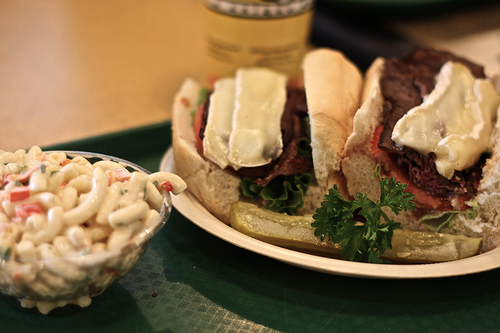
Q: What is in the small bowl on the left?
A: Macaroni Salad.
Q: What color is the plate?
A: White.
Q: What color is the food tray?
A: Green.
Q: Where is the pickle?
A: Plate.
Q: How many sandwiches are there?
A: 2.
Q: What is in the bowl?
A: Macaroni salad.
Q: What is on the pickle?
A: Parsley.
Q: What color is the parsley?
A: Green.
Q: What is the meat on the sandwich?
A: Roast beef.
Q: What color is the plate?
A: White.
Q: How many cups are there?
A: One.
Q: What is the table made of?
A: Wood.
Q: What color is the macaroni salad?
A: Pale yellow.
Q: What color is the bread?
A: Brown.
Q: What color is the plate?
A: White.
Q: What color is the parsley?
A: Green.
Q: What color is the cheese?
A: White.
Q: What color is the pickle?
A: Bright green.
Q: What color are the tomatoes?
A: Red.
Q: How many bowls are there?
A: One.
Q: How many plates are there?
A: One.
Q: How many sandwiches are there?
A: 2.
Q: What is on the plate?
A: A sandwich.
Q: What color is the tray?
A: Green.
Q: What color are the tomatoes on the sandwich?
A: Red.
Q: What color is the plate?
A: White.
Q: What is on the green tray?
A: Lunch.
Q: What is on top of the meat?
A: Mayonnaise.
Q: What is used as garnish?
A: A sprig of parsley.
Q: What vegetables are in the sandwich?
A: Lettuce and tomatoes.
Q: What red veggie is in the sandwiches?
A: Tomatoes.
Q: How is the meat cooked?
A: It has been browned.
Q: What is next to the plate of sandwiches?
A: A bowl of pasta.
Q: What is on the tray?
A: A full plate of sandwiches.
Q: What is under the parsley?
A: A slice of a pickle.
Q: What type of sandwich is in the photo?
A: Pork with cheese on top.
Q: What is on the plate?
A: Two sandwiches.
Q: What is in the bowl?
A: Macaroni salad.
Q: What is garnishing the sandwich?
A: Parsley.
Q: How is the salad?
A: Creamy.